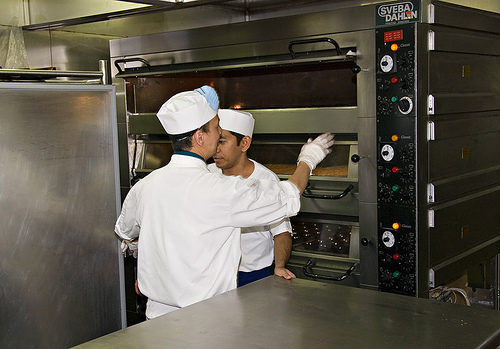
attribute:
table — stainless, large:
[61, 272, 496, 347]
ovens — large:
[106, 0, 497, 312]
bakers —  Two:
[112, 60, 348, 324]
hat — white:
[150, 84, 246, 167]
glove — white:
[295, 126, 337, 174]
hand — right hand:
[294, 129, 338, 174]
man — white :
[112, 82, 337, 322]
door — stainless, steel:
[1, 81, 127, 346]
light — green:
[223, 76, 273, 119]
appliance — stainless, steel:
[110, 9, 498, 300]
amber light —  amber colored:
[387, 213, 404, 235]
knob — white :
[379, 142, 395, 162]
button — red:
[389, 165, 401, 174]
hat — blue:
[123, 65, 245, 150]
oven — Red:
[106, 1, 499, 293]